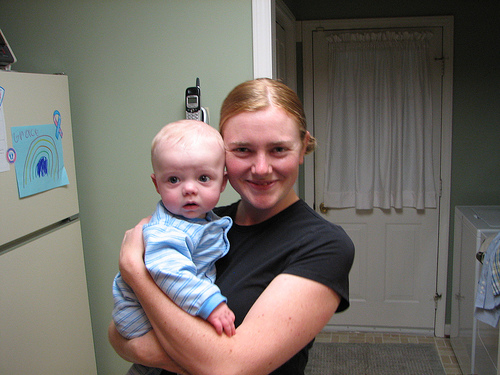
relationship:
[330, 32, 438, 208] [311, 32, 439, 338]
curtain on door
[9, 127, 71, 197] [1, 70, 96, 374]
drawing on fridge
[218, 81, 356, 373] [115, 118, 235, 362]
woman holding up baby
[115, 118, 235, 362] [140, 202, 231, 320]
baby in a onesie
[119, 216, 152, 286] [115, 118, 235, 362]
hand touching baby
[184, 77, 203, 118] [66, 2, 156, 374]
telephone on wall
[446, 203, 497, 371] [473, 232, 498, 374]
washer alongside dryer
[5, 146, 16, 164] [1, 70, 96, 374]
magnet on fridge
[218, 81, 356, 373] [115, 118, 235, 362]
woman holding onto a baby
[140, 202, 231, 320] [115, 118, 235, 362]
onesie on baby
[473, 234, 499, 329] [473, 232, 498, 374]
cloth on dryer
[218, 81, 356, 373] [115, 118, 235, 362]
woman snuggling a baby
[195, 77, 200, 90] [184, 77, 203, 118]
aentenna on telephone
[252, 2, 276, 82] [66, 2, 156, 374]
strip on wall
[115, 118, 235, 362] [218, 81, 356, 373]
baby being held by woman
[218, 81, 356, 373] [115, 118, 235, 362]
woman holding baby